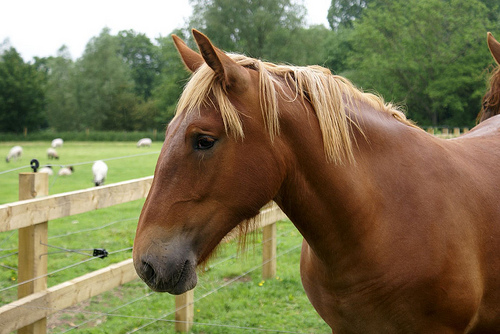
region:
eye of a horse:
[190, 127, 216, 152]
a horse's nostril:
[139, 258, 156, 285]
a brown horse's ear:
[192, 27, 250, 94]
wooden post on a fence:
[16, 170, 46, 332]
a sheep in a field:
[90, 158, 107, 185]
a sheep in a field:
[135, 135, 152, 150]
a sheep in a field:
[4, 145, 22, 161]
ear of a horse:
[170, 34, 202, 76]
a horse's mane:
[174, 50, 409, 168]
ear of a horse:
[485, 30, 499, 69]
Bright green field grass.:
[211, 269, 300, 322]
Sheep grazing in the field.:
[5, 131, 111, 171]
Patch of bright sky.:
[22, 7, 162, 49]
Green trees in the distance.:
[10, 32, 163, 132]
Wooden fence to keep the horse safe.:
[0, 172, 145, 231]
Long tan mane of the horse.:
[271, 72, 392, 178]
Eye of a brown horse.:
[178, 118, 232, 163]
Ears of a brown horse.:
[165, 18, 255, 96]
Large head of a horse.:
[77, 14, 347, 292]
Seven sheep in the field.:
[0, 130, 154, 180]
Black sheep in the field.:
[27, 158, 39, 173]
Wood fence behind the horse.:
[0, 165, 300, 330]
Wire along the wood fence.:
[0, 243, 143, 295]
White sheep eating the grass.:
[88, 158, 111, 186]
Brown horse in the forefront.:
[129, 25, 498, 332]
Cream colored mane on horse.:
[164, 30, 430, 175]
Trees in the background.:
[2, 5, 497, 127]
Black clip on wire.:
[88, 245, 112, 264]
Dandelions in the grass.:
[255, 273, 268, 288]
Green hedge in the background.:
[10, 130, 172, 141]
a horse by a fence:
[121, 9, 498, 331]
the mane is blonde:
[150, 29, 427, 179]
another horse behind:
[460, 21, 499, 130]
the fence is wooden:
[1, 146, 297, 332]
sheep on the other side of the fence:
[5, 129, 158, 194]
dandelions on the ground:
[254, 280, 281, 289]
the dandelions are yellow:
[248, 274, 278, 291]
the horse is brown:
[112, 13, 496, 330]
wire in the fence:
[4, 154, 308, 329]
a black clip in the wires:
[86, 248, 116, 258]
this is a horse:
[131, 44, 486, 331]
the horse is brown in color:
[399, 174, 481, 289]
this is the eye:
[193, 130, 216, 148]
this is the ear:
[196, 24, 222, 89]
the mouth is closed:
[151, 241, 194, 282]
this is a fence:
[42, 176, 109, 323]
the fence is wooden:
[42, 190, 92, 211]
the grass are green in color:
[235, 279, 297, 319]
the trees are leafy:
[381, 20, 459, 93]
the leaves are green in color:
[386, 5, 479, 82]